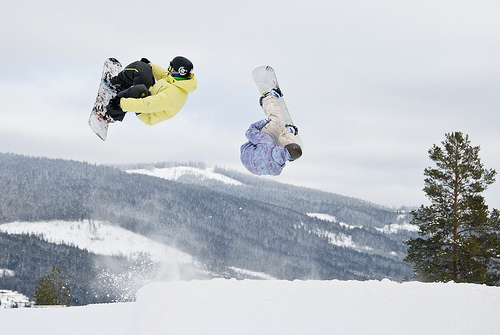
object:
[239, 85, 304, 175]
person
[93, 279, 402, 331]
snowy surface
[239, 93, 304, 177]
man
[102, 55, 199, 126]
person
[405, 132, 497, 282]
leaves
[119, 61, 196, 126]
jacket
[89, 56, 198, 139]
outfit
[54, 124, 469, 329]
hill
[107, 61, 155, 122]
black pants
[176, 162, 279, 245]
snow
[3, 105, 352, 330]
hill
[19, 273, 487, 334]
snow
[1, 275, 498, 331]
snow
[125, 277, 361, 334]
snow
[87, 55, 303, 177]
snowboarders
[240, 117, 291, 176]
coat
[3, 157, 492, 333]
ground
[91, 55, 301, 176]
men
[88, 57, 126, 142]
board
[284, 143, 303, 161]
helmet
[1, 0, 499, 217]
cloud cover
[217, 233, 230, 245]
tree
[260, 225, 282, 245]
tree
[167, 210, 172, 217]
tree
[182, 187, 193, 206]
tree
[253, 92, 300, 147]
pants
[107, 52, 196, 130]
person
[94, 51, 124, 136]
snowboard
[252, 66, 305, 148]
board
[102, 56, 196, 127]
man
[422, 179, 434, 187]
needles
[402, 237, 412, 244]
needles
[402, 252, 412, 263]
needles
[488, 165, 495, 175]
needles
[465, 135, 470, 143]
needles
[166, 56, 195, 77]
helmet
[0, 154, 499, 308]
hill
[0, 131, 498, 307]
trees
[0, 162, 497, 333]
snow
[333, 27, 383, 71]
sky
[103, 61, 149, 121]
legs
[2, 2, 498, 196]
sky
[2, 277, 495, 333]
foreground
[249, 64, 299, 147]
snowboard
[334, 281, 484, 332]
mountain side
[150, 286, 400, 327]
snow